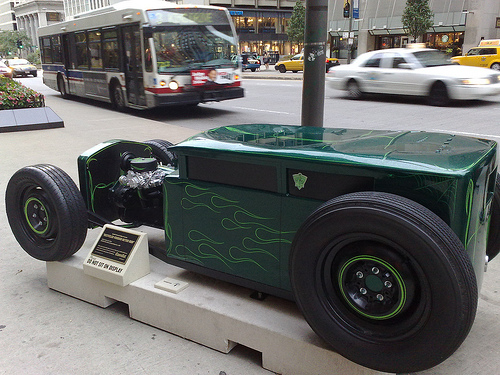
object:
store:
[326, 3, 500, 61]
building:
[63, 0, 305, 63]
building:
[15, 0, 63, 59]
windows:
[237, 11, 303, 59]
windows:
[365, 29, 460, 53]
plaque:
[87, 227, 142, 274]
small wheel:
[5, 163, 88, 263]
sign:
[353, 0, 360, 19]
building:
[322, 0, 499, 58]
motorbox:
[5, 162, 479, 372]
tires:
[287, 190, 480, 373]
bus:
[37, 0, 246, 113]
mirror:
[398, 63, 413, 68]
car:
[274, 53, 340, 74]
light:
[168, 81, 179, 90]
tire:
[110, 79, 127, 113]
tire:
[429, 80, 450, 106]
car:
[326, 47, 499, 106]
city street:
[0, 0, 500, 147]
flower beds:
[0, 71, 46, 111]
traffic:
[0, 11, 499, 375]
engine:
[110, 152, 177, 228]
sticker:
[292, 173, 308, 191]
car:
[240, 53, 261, 73]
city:
[0, 0, 500, 375]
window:
[102, 30, 128, 66]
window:
[87, 32, 102, 68]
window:
[71, 35, 88, 65]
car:
[450, 39, 498, 70]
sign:
[191, 68, 239, 87]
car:
[4, 123, 499, 374]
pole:
[300, 0, 328, 125]